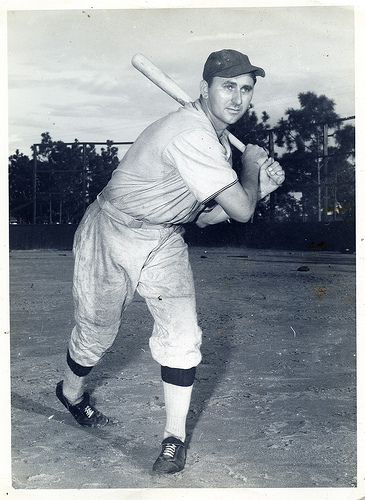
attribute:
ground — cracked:
[13, 244, 363, 485]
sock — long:
[156, 384, 203, 452]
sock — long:
[62, 361, 85, 406]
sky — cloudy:
[39, 26, 115, 103]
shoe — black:
[151, 436, 187, 474]